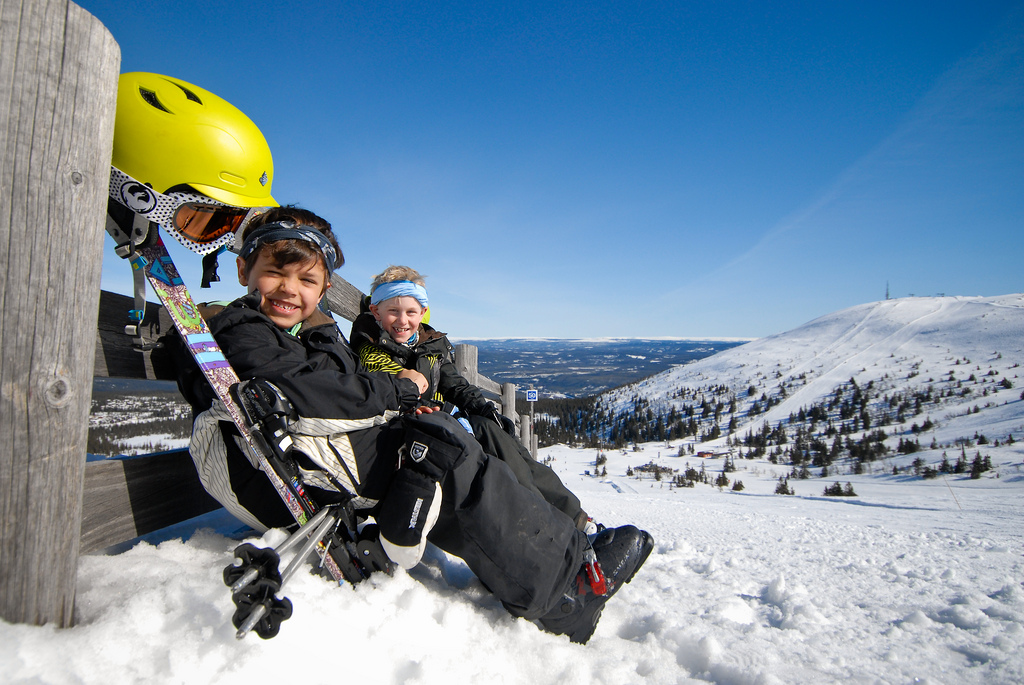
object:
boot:
[521, 524, 652, 651]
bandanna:
[236, 220, 339, 279]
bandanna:
[369, 280, 432, 310]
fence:
[0, 0, 545, 630]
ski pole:
[84, 196, 401, 597]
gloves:
[354, 416, 470, 571]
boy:
[161, 202, 654, 651]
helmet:
[106, 62, 295, 271]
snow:
[337, 608, 486, 681]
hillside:
[553, 305, 1024, 493]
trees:
[780, 368, 895, 509]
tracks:
[720, 532, 846, 643]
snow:
[707, 571, 820, 647]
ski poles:
[196, 505, 364, 646]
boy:
[345, 260, 604, 578]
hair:
[234, 204, 347, 285]